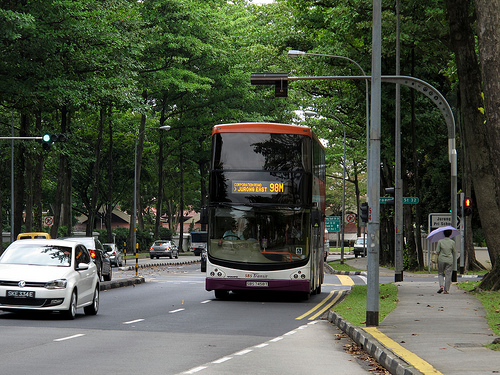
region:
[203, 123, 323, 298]
Airconditioned city bus in Singapore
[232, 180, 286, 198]
Name of the destination and route number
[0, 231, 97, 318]
White car on the road.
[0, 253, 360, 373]
The road with a crossing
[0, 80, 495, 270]
Trees on both sides of the road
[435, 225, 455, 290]
A woman walking on the sidewalk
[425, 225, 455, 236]
Lavender colored umbrella that a woman is carrying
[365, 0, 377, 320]
Electricity pole of the street light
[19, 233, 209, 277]
Cars going other the other side f the divider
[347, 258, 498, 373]
Clean and cemented side walk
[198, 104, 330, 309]
the double decker bus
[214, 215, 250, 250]
the driver of the bus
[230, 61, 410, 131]
traffic light over the street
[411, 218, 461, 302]
the woman with umbrella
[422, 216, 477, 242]
the umbrella is purple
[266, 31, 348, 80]
street light over the street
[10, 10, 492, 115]
trees with green leaves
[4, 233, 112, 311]
the car on the street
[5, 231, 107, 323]
the car is white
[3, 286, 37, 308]
the license plate on the car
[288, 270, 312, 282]
the headlights of a bus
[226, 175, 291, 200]
a digital display on the bus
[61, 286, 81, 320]
a wheel on the car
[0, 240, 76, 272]
the windshield of a car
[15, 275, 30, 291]
a logo on the car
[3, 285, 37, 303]
a black license plate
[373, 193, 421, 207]
a green street sign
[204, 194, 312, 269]
a windshield of the bus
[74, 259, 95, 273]
a side view mirror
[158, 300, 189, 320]
a white stripe in the road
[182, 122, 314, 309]
Double decker bus in the road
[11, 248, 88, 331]
White color car on the road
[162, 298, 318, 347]
A road marked with white and yellow color line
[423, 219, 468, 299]
A person walking on the side walk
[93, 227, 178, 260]
Lot of cars parked in the parking area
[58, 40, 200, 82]
Lot of trees with branches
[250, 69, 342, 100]
Traffic signal metal post with lights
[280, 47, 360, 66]
Street lights with metal post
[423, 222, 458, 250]
A person holding an umbrella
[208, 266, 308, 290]
Head lights and number plate of the bus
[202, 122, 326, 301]
an oncoming bus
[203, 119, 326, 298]
an oncoming red and white bus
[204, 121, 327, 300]
an oncoming double-decker bus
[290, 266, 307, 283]
three lights on the bus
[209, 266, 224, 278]
three lights on the bus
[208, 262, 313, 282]
very small head lights on the bus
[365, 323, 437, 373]
yellow stripe by the road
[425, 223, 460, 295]
woman walking with an umbrella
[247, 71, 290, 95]
traffic signal above the bus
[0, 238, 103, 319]
white sedan in the road